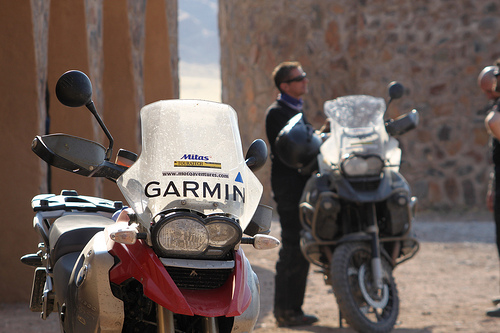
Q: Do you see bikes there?
A: Yes, there is a bike.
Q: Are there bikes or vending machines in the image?
A: Yes, there is a bike.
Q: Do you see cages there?
A: No, there are no cages.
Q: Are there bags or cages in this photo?
A: No, there are no cages or bags.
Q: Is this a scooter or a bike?
A: This is a bike.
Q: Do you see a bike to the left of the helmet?
A: Yes, there is a bike to the left of the helmet.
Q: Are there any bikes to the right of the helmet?
A: No, the bike is to the left of the helmet.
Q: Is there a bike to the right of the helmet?
A: No, the bike is to the left of the helmet.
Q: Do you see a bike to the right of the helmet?
A: No, the bike is to the left of the helmet.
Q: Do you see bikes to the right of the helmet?
A: No, the bike is to the left of the helmet.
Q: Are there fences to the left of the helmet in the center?
A: No, there is a bike to the left of the helmet.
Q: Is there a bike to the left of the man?
A: Yes, there is a bike to the left of the man.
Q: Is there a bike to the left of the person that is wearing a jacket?
A: Yes, there is a bike to the left of the man.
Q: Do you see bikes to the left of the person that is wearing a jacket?
A: Yes, there is a bike to the left of the man.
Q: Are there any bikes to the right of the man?
A: No, the bike is to the left of the man.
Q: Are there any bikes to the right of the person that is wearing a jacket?
A: No, the bike is to the left of the man.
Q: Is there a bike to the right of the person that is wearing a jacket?
A: No, the bike is to the left of the man.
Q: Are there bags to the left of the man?
A: No, there is a bike to the left of the man.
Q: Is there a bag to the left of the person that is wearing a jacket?
A: No, there is a bike to the left of the man.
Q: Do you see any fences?
A: No, there are no fences.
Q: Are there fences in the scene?
A: No, there are no fences.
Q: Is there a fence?
A: No, there are no fences.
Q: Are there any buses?
A: No, there are no buses.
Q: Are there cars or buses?
A: No, there are no buses or cars.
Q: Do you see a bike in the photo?
A: Yes, there is a bike.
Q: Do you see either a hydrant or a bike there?
A: Yes, there is a bike.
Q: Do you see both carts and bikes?
A: No, there is a bike but no carts.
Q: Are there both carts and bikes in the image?
A: No, there is a bike but no carts.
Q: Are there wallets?
A: No, there are no wallets.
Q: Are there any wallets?
A: No, there are no wallets.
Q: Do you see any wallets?
A: No, there are no wallets.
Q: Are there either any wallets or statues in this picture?
A: No, there are no wallets or statues.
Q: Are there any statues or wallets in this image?
A: No, there are no wallets or statues.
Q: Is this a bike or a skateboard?
A: This is a bike.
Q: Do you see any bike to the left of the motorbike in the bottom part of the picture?
A: No, the bike is to the right of the motorcycle.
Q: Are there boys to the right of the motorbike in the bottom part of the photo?
A: No, there is a bike to the right of the motorbike.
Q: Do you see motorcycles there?
A: Yes, there are motorcycles.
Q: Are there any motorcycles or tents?
A: Yes, there are motorcycles.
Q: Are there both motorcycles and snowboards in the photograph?
A: No, there are motorcycles but no snowboards.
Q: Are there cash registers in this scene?
A: No, there are no cash registers.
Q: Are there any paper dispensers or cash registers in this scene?
A: No, there are no cash registers or paper dispensers.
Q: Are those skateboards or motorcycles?
A: Those are motorcycles.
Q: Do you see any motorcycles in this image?
A: Yes, there is a motorcycle.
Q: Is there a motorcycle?
A: Yes, there is a motorcycle.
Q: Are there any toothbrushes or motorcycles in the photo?
A: Yes, there is a motorcycle.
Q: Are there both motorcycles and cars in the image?
A: No, there is a motorcycle but no cars.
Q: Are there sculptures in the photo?
A: No, there are no sculptures.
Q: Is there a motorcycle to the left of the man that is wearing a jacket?
A: Yes, there is a motorcycle to the left of the man.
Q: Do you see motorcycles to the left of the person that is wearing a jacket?
A: Yes, there is a motorcycle to the left of the man.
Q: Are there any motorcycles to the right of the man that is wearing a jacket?
A: No, the motorcycle is to the left of the man.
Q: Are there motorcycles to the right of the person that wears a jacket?
A: No, the motorcycle is to the left of the man.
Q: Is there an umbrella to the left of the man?
A: No, there is a motorcycle to the left of the man.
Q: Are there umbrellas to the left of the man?
A: No, there is a motorcycle to the left of the man.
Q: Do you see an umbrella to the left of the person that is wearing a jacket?
A: No, there is a motorcycle to the left of the man.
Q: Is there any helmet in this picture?
A: Yes, there is a helmet.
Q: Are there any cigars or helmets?
A: Yes, there is a helmet.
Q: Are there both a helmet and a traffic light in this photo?
A: No, there is a helmet but no traffic lights.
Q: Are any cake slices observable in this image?
A: No, there are no cake slices.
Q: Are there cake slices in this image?
A: No, there are no cake slices.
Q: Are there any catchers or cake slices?
A: No, there are no cake slices or catchers.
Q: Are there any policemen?
A: No, there are no policemen.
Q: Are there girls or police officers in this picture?
A: No, there are no police officers or girls.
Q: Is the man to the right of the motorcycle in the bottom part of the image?
A: Yes, the man is to the right of the motorbike.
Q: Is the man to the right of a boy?
A: No, the man is to the right of the motorbike.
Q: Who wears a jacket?
A: The man wears a jacket.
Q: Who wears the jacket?
A: The man wears a jacket.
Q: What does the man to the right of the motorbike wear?
A: The man wears a jacket.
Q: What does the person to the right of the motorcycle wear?
A: The man wears a jacket.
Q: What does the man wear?
A: The man wears a jacket.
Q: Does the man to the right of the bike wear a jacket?
A: Yes, the man wears a jacket.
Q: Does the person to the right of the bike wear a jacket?
A: Yes, the man wears a jacket.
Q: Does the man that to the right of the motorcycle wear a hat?
A: No, the man wears a jacket.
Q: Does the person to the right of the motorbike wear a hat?
A: No, the man wears a jacket.